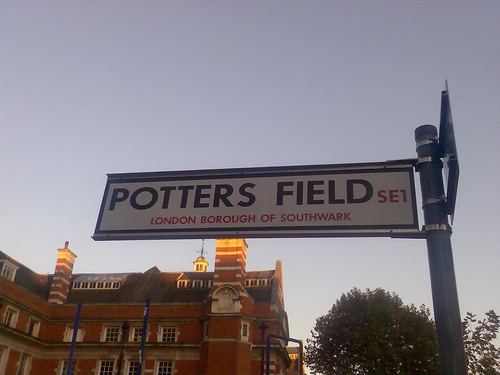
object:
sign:
[91, 157, 428, 241]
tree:
[303, 285, 441, 375]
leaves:
[395, 318, 432, 349]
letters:
[235, 181, 257, 208]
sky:
[0, 0, 500, 375]